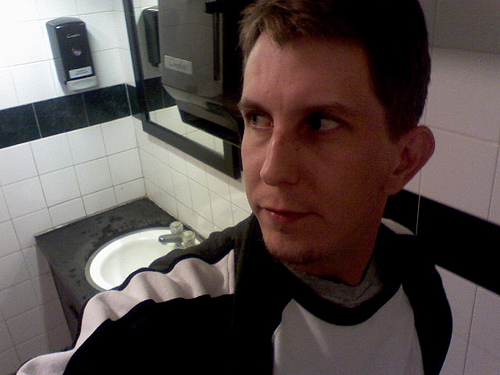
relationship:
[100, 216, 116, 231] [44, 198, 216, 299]
water on counter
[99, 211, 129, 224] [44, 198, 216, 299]
splashes on counter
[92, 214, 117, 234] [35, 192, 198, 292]
splashes on counter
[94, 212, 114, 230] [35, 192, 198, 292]
water on counter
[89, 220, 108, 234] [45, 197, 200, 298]
water on counter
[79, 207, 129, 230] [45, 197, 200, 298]
splashes on counter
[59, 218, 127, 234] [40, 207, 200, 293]
water on counter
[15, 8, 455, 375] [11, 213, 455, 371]
man in shirt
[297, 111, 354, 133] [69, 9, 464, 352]
eye of man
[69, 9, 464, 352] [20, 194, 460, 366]
man in shirt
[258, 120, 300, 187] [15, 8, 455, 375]
nose of man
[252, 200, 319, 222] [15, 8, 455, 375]
mouth of man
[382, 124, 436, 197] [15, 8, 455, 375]
ear of man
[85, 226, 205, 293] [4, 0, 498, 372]
sink in bathroom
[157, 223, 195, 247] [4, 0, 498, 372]
faucet in bathroom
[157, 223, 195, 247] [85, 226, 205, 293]
faucet of sink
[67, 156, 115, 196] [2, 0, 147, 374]
tile part of wall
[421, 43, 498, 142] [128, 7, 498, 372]
tile part of wall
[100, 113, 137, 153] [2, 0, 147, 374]
tile on wall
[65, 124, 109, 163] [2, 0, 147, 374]
tile on wall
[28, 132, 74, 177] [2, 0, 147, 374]
tile on wall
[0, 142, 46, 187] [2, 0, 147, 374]
tile on wall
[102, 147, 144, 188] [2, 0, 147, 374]
tile on wall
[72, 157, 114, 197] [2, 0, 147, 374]
tile on wall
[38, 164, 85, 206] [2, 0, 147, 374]
tile on wall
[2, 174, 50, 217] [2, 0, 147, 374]
tile on wall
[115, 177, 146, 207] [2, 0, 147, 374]
tile on wall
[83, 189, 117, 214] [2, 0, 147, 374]
tile on wall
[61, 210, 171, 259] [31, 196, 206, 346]
water on sink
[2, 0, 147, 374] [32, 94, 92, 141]
wall has tile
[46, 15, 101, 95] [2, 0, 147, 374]
soap dispenser on wall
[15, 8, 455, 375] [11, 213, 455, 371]
man has a shirt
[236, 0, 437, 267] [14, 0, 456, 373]
head of a person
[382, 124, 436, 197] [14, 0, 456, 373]
ear of a person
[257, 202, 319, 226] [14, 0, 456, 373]
mouth of a person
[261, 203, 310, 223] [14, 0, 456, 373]
lips of a person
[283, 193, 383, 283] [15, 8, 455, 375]
neck of man